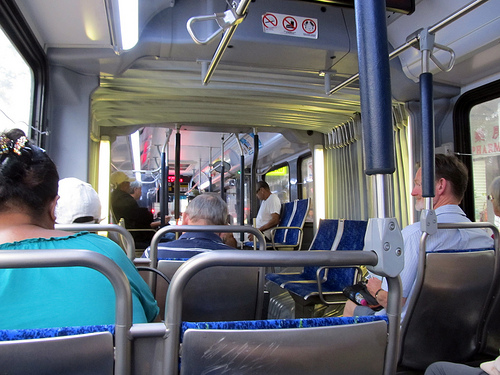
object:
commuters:
[0, 132, 500, 340]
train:
[0, 0, 490, 366]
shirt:
[257, 186, 289, 250]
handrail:
[185, 8, 247, 50]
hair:
[0, 124, 61, 219]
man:
[141, 191, 242, 261]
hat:
[56, 176, 104, 228]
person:
[45, 178, 159, 318]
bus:
[3, 4, 489, 374]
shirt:
[0, 234, 162, 345]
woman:
[5, 121, 155, 337]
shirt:
[141, 223, 245, 262]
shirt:
[371, 205, 495, 324]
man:
[243, 178, 284, 244]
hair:
[427, 150, 470, 206]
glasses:
[255, 188, 263, 194]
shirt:
[255, 193, 282, 239]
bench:
[266, 218, 368, 301]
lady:
[0, 124, 160, 333]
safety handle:
[176, 50, 200, 54]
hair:
[187, 194, 228, 224]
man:
[343, 148, 494, 317]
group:
[0, 137, 494, 329]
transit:
[129, 107, 274, 147]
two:
[159, 152, 499, 345]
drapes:
[320, 110, 412, 229]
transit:
[27, 124, 352, 354]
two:
[115, 174, 163, 235]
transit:
[50, 175, 466, 375]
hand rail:
[406, 36, 459, 72]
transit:
[86, 105, 354, 264]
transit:
[0, 0, 498, 375]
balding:
[202, 195, 214, 201]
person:
[108, 178, 172, 245]